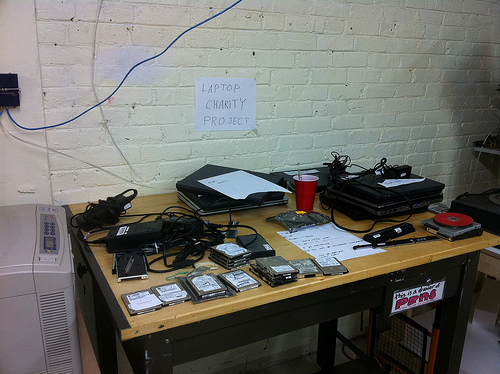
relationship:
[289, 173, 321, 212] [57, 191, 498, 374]
cup on desk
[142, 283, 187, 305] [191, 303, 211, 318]
disk on desk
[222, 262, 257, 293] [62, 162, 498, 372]
disk on desk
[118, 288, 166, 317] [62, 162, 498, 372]
disk on desk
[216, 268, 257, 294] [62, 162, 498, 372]
disk on desk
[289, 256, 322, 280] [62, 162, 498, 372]
disk on desk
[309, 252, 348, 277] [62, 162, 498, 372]
disk on desk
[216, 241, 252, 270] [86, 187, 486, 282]
disk on desk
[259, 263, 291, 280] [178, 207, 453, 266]
disk on desk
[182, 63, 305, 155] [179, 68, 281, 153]
sign has text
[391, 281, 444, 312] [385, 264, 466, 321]
label on drawer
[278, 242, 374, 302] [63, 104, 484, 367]
disk on desk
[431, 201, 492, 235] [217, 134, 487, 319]
disk on desk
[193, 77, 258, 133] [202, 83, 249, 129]
sign has text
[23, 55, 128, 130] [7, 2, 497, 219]
cord against wall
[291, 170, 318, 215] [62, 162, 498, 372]
cup on desk